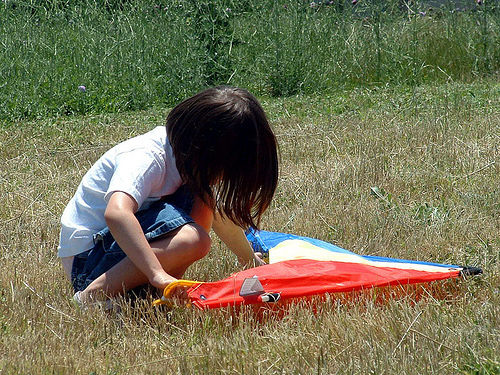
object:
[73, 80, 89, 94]
flower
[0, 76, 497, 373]
field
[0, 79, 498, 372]
grass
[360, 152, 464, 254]
dandelions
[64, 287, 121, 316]
sneaker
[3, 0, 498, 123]
bushes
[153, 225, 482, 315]
toy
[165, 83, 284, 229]
hair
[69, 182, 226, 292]
skirt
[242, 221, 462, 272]
section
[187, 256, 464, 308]
section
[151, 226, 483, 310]
kite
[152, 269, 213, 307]
holder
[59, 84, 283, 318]
girl